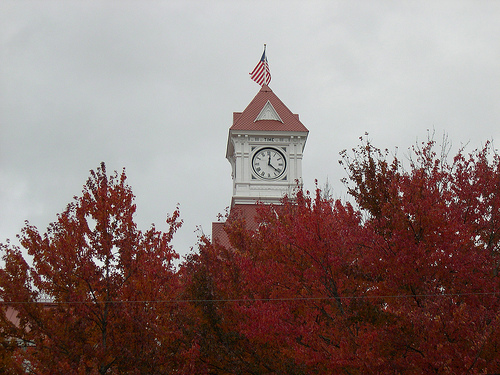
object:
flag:
[247, 45, 272, 86]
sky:
[0, 0, 246, 110]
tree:
[218, 249, 438, 358]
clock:
[248, 144, 289, 182]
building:
[213, 83, 309, 243]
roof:
[229, 108, 309, 131]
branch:
[101, 261, 112, 334]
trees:
[96, 163, 113, 375]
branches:
[112, 266, 134, 295]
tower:
[224, 81, 310, 253]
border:
[248, 149, 256, 177]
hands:
[267, 154, 272, 165]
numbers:
[261, 171, 265, 176]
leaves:
[151, 222, 155, 226]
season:
[0, 191, 500, 316]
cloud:
[97, 45, 193, 81]